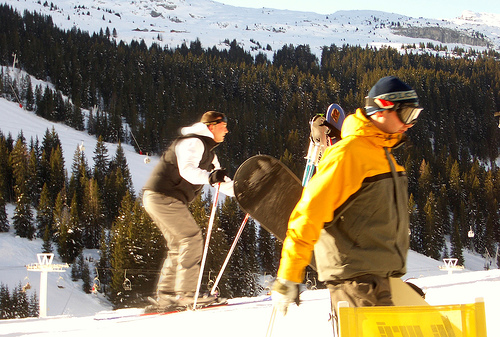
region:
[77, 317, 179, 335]
very clean fresh white snow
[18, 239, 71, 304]
tall white cross on the snow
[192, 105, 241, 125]
turned around brown cap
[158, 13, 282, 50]
trees on the snow covered mountain top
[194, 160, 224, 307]
ski pole in skier's hand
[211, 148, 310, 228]
edge of ski board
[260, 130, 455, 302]
yellow and gray ski jacket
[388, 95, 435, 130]
black and yellow goggles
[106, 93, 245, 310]
skier crouching on board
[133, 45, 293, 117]
evergreen trees in the valley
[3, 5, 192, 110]
pine forest in winter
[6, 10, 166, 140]
pine forest amidst snow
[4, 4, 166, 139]
pine forest in a snowy mountain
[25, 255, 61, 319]
white ski lift support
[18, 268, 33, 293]
ski lift buggy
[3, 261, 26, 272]
strong cable of ski lift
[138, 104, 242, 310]
man on skis moving uphill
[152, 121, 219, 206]
white sweatshirt under a black vest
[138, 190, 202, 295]
man wearing khaki pants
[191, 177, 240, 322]
set of white and red ski poles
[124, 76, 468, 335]
skier riding on the mountain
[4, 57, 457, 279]
snow on the ski slope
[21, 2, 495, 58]
snow on the top of the hill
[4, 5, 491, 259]
a row of trees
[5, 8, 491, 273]
the fir trees are dark green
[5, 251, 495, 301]
carts on the ski lift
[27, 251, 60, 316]
a pole on the ski lift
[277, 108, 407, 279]
a man wearing a yellow jacket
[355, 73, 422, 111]
a man wearing a hat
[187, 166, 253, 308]
a man holding skies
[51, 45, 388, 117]
The background is a forest.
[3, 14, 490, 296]
This is on a ski slope.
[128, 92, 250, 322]
This man is skiing.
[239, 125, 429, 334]
This man is snowboarding.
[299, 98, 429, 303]
This man's jacket is yellow and gray.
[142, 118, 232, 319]
This man has a black vest on.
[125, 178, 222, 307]
His pants are gray.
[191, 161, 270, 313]
He is holding two poles.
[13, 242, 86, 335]
This is part of a ski lift.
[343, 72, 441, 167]
This man has googles on.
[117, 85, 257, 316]
a man standing on a ski slope.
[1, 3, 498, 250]
a forest filled with green trees.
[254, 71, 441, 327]
a man wearing a jacket.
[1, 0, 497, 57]
the top of snow capped mountains.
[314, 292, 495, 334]
a chair on a snow covered slope.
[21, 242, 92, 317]
a white ski lift.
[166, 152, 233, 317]
a left ski pole.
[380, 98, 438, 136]
a pair of goggles.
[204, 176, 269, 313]
a left ski pole.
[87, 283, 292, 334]
a ski on the snow.